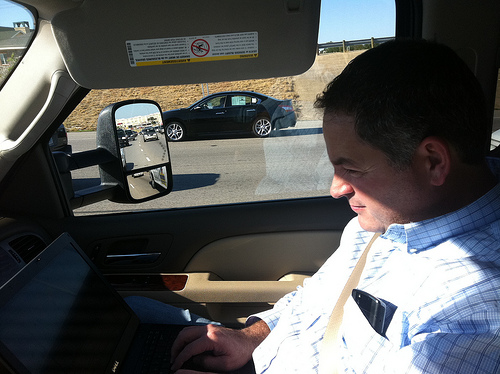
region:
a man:
[159, 31, 494, 372]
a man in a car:
[111, 33, 496, 372]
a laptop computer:
[3, 231, 258, 371]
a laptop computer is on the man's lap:
[3, 40, 499, 368]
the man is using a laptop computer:
[6, 28, 495, 372]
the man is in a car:
[1, 0, 493, 370]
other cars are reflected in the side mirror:
[98, 95, 178, 200]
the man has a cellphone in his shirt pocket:
[343, 282, 392, 354]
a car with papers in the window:
[157, 85, 304, 142]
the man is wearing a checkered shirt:
[166, 36, 498, 367]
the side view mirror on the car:
[110, 97, 172, 202]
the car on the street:
[160, 90, 297, 141]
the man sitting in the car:
[122, 37, 498, 372]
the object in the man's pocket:
[351, 287, 386, 336]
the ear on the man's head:
[420, 135, 450, 187]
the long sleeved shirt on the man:
[243, 183, 498, 372]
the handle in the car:
[0, 67, 75, 159]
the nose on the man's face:
[330, 169, 353, 199]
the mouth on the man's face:
[349, 203, 366, 208]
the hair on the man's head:
[312, 36, 494, 168]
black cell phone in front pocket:
[350, 283, 395, 340]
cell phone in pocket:
[347, 276, 387, 341]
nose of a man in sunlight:
[326, 170, 354, 202]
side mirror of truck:
[88, 95, 181, 205]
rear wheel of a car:
[250, 115, 275, 137]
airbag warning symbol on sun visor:
[115, 30, 267, 68]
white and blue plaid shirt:
[239, 208, 497, 365]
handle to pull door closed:
[203, 266, 303, 293]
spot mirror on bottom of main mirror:
[122, 165, 174, 205]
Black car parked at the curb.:
[161, 88, 297, 140]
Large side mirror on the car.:
[92, 85, 176, 214]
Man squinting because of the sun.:
[312, 37, 476, 244]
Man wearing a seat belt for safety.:
[307, 233, 382, 370]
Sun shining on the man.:
[230, 235, 471, 372]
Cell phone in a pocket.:
[329, 278, 395, 363]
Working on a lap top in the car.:
[10, 221, 292, 366]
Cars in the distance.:
[98, 92, 170, 155]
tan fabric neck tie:
[323, 229, 380, 321]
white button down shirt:
[247, 194, 499, 371]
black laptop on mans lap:
[3, 232, 205, 372]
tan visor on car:
[50, 3, 322, 83]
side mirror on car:
[71, 98, 173, 203]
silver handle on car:
[106, 245, 161, 265]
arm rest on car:
[109, 268, 310, 308]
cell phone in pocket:
[351, 287, 392, 336]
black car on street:
[151, 89, 296, 141]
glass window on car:
[203, 95, 227, 110]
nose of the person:
[321, 158, 368, 205]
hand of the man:
[170, 282, 275, 372]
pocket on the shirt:
[299, 286, 399, 368]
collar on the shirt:
[353, 189, 485, 273]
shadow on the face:
[346, 158, 419, 238]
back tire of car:
[239, 111, 284, 148]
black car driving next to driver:
[154, 82, 303, 143]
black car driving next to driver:
[152, 85, 309, 142]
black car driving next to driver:
[140, 82, 303, 145]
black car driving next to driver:
[146, 75, 308, 152]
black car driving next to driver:
[146, 83, 301, 151]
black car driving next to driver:
[142, 75, 301, 150]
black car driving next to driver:
[146, 75, 303, 146]